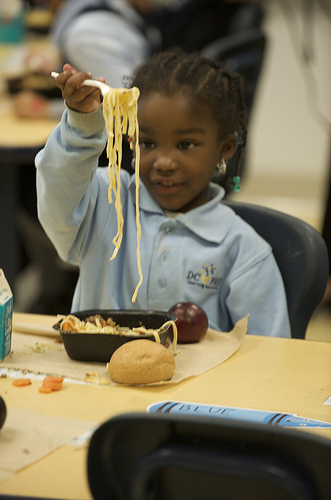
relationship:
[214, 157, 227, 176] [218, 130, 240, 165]
earring on ear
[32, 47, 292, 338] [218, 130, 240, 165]
girl has ear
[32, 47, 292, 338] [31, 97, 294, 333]
girl wearing shirt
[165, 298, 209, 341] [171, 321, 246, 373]
apple on napkin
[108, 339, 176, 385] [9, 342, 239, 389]
bread roll on napkin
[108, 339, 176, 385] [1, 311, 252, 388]
bread roll on napkin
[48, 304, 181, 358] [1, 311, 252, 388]
lunch item on napkin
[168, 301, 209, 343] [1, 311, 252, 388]
apple on napkin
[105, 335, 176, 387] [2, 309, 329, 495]
bread roll on table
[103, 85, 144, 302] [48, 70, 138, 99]
noodles on fork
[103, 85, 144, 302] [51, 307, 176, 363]
noodles above bowl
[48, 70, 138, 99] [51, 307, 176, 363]
fork above bowl